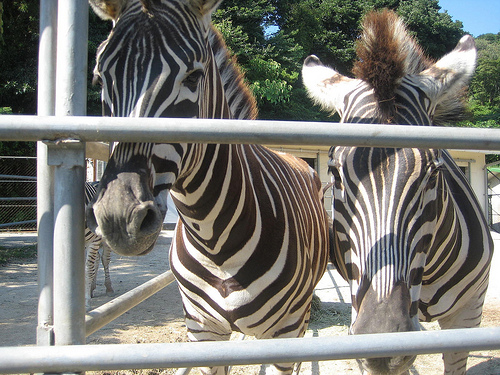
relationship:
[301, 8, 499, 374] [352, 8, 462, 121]
zebra has a mane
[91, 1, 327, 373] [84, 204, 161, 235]
zebra has a nostrills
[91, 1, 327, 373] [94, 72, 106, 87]
zebra has an eye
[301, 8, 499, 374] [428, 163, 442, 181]
zebra has an eye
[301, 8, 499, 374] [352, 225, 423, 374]
zebra has a muzzle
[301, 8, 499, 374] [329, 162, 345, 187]
zebra has a eye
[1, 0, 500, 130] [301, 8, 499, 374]
trees are behind zebra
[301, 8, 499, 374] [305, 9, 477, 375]
zebra has a head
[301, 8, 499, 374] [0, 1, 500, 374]
zebra in a pen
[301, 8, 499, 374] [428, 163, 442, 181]
zebra has a eye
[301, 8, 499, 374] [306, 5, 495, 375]
zebra has fur